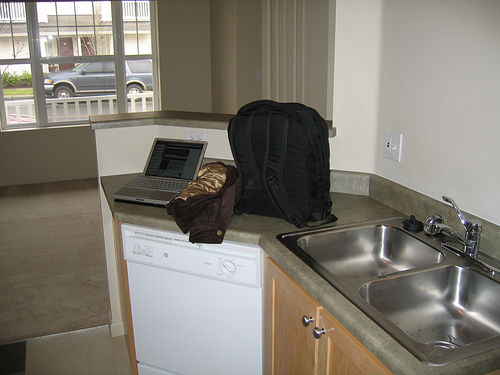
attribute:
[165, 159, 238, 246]
jacket — brown, gold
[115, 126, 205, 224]
laptop — open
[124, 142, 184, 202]
laptop — silver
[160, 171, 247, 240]
jacket — brown, gold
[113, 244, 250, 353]
dishwasher — white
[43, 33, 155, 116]
frame — white, window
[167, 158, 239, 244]
dark/brown jacket — with tan lining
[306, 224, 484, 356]
sink — silver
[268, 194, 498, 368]
sink — silver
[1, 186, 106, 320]
carpet — tan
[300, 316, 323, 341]
hardware — silver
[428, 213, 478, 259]
faucet — silver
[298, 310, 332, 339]
knobs — silver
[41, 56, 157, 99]
car — blue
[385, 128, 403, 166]
light switch — white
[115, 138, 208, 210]
laptop — silver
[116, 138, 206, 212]
computer — silver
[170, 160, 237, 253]
coat — brown, gold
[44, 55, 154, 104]
suv — blue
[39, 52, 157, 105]
suv — blue, large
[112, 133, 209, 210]
laptop — small, gray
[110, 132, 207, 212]
computer — small, gray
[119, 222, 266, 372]
dishwasher — white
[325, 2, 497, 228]
wall — white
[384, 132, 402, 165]
outlet — white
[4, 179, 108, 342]
carpet — beige, brown